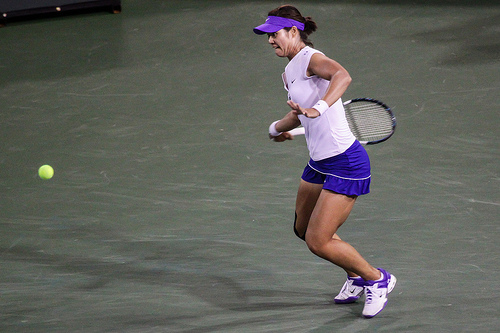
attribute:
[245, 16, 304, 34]
visor — purple in color, purple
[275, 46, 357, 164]
shirt — white, nike polo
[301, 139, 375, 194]
skirt — blue in color, blue, short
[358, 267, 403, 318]
shoe — white in color, white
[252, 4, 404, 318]
woman — playing tennis, female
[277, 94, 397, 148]
racket — white in color, black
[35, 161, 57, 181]
ball — moving, in air, yellow, for tennis, green in color, green colored, green shaded, green color, green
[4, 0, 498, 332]
ground — grey, scratched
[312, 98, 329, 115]
sweatband — white colored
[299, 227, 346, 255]
knee — bent